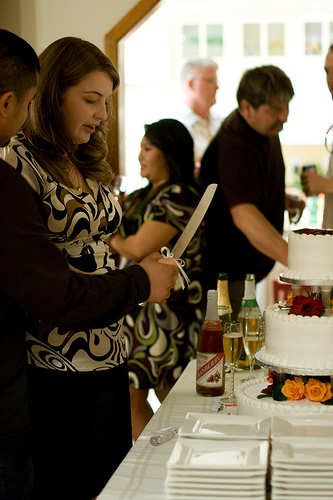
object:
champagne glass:
[220, 320, 243, 406]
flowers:
[256, 369, 333, 406]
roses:
[278, 375, 332, 404]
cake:
[235, 376, 333, 416]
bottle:
[217, 273, 233, 334]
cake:
[235, 227, 333, 417]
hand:
[140, 252, 179, 306]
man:
[0, 27, 179, 500]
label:
[197, 352, 223, 388]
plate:
[271, 417, 333, 441]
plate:
[269, 438, 333, 500]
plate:
[167, 439, 268, 500]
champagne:
[242, 316, 262, 384]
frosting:
[271, 313, 306, 320]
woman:
[4, 38, 132, 500]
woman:
[106, 117, 202, 441]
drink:
[224, 331, 243, 364]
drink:
[243, 331, 262, 356]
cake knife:
[143, 182, 218, 307]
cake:
[254, 303, 333, 377]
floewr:
[289, 294, 326, 318]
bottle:
[195, 290, 225, 398]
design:
[47, 325, 122, 372]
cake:
[278, 227, 333, 287]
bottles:
[236, 273, 262, 370]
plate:
[177, 411, 271, 439]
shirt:
[1, 129, 127, 373]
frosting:
[267, 307, 329, 335]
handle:
[231, 366, 235, 399]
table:
[96, 360, 333, 500]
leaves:
[256, 383, 286, 399]